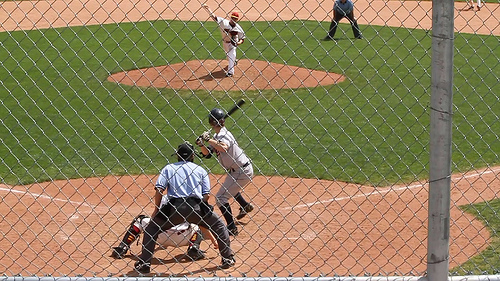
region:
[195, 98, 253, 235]
a baseball player about to hit a ball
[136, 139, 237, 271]
an umpire standing behind a catcher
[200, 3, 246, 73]
a pitcher about to pitch a ball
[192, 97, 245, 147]
baseball player holding a baseball bat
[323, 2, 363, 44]
person standing with their hand on their knees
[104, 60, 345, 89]
a pitcher's mound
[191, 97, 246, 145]
a black baseball bat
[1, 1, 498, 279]
a metal fence in a baseball field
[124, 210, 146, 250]
a catcher wearing knee protection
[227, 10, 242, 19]
a pitcher wearing a cap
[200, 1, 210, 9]
Baseball in pitcher's right hand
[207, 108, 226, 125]
Helmet on batter's head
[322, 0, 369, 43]
Umpire in the grass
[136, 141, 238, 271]
Umpire behind a catcher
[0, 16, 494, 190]
Grass on a baseball infield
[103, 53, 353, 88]
Pitcher's mound on a baseball field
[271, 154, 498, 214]
White line on a baseball field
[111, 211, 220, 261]
Catcher's legs in front of an umpire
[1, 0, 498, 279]
Fence behind baseball players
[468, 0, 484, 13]
Fielder in the dirt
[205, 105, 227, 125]
The helmet is black.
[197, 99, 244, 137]
His bat is black.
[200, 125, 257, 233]
His jersey is gray.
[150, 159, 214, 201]
The shirt is blue.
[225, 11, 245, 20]
His hat is red.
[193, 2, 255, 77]
The pitcher is throwing the ball.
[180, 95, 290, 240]
He is hitting the ball.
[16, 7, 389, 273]
They are playing baseball.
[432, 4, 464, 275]
The pole is metal.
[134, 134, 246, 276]
The ump is standing.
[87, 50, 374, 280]
people playing baseball players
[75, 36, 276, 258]
a men playing baseball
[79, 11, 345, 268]
men on a baseball field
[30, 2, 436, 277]
a field with baseball players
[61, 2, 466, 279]
a field with player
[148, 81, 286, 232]
baseball players holding a bat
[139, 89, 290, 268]
a baseball player in uniform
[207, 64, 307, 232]
a baseball player in a unfiorm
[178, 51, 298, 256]
a player swinging a bat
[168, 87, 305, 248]
a player hodling a bat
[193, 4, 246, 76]
player throwing ball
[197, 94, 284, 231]
player holding the bat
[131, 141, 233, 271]
umpire behind the catcher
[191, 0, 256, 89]
pitcher on the mound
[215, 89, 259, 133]
bat in the hand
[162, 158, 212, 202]
shirt on the umpire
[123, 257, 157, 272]
shoe on the umpire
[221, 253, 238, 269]
shoe on the umpire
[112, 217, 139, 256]
protective gear on the catcher leg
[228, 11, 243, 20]
hat on the pitcher